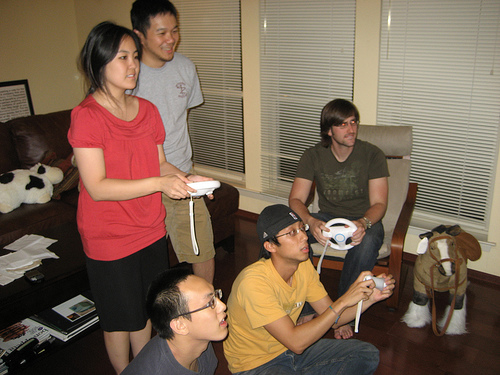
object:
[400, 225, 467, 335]
horse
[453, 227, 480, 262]
saddle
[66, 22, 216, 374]
woman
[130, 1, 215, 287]
man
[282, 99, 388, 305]
man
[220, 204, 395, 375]
guy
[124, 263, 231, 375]
guy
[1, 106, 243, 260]
couch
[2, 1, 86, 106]
wall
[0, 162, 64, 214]
cow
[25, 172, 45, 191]
spot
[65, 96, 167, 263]
top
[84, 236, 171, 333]
skirt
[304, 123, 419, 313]
chair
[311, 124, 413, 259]
cushion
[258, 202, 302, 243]
cap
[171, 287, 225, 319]
glasses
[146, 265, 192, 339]
hair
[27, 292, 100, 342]
book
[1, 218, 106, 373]
coffee table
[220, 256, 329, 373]
tshirt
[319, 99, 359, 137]
hair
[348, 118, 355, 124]
eye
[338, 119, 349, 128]
eye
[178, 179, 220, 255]
controller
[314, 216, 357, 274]
steering wheel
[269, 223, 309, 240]
glasses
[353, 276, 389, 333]
controller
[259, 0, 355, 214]
blinds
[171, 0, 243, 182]
blinds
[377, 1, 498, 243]
blinds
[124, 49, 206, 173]
tshirt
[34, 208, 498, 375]
floor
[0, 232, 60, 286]
papers